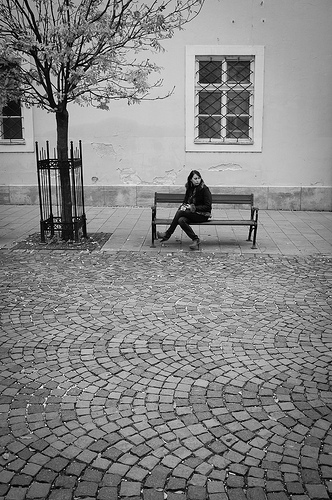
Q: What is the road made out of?
A: Cobblestone.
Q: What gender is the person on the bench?
A: Female.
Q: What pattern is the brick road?
A: Swirls.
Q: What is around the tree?
A: Protective fence.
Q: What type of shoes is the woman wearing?
A: High heel.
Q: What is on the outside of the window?
A: Metal.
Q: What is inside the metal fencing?
A: Tree.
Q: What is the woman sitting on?
A: Bench.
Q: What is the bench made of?
A: Metal and wood.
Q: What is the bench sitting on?
A: Sidewalk.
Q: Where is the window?
A: The wall.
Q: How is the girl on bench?
A: Alone.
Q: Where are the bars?
A: On window.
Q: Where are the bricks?
A: A patio.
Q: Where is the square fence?
A: Around the tree.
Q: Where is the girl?
A: On bench.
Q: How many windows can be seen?
A: Two.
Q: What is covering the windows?
A: Grills.